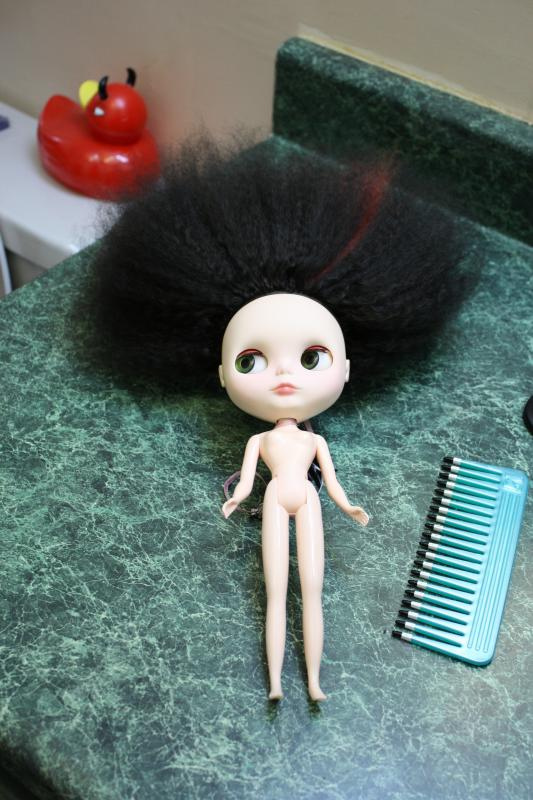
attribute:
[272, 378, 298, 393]
mouth — pink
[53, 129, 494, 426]
hair — black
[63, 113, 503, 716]
doll — naked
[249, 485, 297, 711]
legs — long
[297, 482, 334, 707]
legs — long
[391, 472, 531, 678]
comb — green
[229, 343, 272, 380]
eyes — round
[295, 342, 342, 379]
eyes — round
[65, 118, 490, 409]
hair — black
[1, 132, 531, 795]
countertop — green, black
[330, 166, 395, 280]
streak — red 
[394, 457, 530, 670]
comb — plastic, green, blue 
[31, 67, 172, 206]
duck — red, rubber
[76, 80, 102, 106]
beak — yellow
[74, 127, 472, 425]
hair — black , red 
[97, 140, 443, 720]
doll — small 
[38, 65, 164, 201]
duck — red